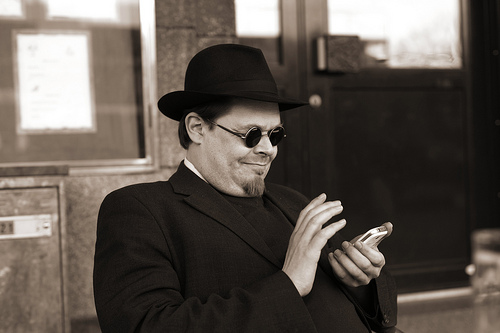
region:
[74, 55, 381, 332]
this is a man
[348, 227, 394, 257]
this is a cell phone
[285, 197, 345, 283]
these are the fingers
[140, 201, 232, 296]
this is a suit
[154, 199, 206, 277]
the suit is black in color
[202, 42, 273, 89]
this is a hat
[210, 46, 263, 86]
the hat is black in color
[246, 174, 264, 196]
this is the beard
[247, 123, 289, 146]
this is the goggles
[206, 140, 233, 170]
the man is light skinned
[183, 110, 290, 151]
sunglasses on the face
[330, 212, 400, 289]
hand cradling a cellphone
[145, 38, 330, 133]
black hat on the head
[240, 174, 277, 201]
hair on the chin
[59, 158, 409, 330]
black suit jacket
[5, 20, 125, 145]
sign on the window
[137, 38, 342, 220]
head is tilted down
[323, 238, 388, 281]
fingers wrapped around the phone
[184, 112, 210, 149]
ear on the side of the head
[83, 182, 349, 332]
arm is bent at the elbow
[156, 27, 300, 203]
head of a person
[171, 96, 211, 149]
ear of a person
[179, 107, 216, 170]
an ear of a person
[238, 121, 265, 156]
eye of a person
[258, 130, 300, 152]
eye of a person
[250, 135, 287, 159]
nose of a person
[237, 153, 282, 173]
mouth of a person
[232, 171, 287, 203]
beard of a person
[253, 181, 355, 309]
hand of a person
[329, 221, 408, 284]
hand of a person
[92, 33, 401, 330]
a man looking at his cellphone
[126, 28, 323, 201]
a man who is wearing a black hat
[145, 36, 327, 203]
a man who is wearing sunglasses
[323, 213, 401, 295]
a man's hand holding a cellphone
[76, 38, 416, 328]
a man wearing a black suit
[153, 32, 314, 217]
a man wearing a goatee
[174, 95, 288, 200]
the head of a man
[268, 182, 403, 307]
the hands of a man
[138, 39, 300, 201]
a man with short hair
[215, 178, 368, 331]
Man wearing a shirt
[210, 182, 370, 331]
Man wearing a dark colored shirt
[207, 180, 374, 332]
Man is wearing a dark colored shirt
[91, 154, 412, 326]
Man wearing a blazer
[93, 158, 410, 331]
Man is wearing a blazer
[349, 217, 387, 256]
Man is holding a phone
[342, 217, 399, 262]
Man is holding a cell phone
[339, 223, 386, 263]
Man holding a cell phone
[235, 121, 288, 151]
round black sunglasses on face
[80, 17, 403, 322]
man smiling at phone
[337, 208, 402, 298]
hand holding iphone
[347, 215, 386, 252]
white iphone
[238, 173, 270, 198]
brown goatee on chin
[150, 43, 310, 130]
black felt hat with round brim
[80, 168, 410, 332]
black jacket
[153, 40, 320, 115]
a simple black fedora hat with a band on it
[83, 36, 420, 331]
a man semi formally dressed sitting down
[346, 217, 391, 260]
a white and metal apple phone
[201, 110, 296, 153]
a pair of sunglasses with round frames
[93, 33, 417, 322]
a man looking at his phone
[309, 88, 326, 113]
a round key hole on a door